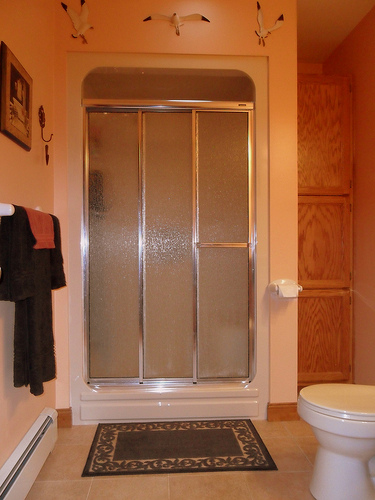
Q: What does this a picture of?
A: A bathroom.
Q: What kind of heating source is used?
A: Baseboard heater.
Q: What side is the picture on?
A: Left.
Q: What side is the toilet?
A: Right.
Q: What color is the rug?
A: Green.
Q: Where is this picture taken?
A: A bathroom.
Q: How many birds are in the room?
A: Three.